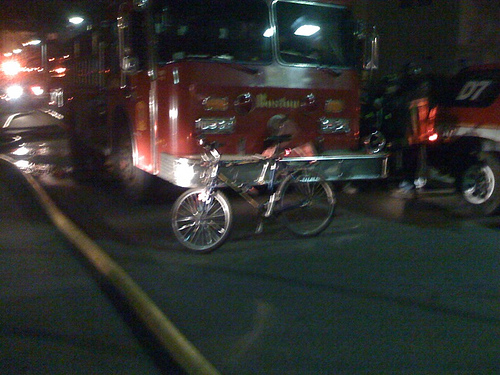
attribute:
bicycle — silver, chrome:
[162, 120, 335, 250]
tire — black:
[442, 156, 492, 202]